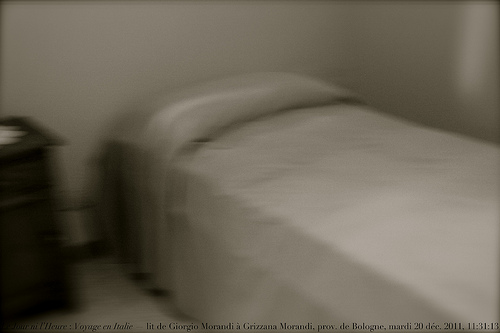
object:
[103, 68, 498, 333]
bed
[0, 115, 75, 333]
dresser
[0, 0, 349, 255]
wall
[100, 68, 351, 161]
pillows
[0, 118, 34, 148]
papers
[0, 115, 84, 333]
table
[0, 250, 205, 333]
ground